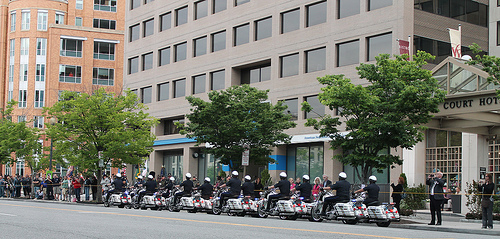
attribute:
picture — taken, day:
[35, 18, 485, 222]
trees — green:
[52, 94, 287, 177]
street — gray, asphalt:
[28, 203, 265, 238]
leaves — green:
[104, 109, 140, 141]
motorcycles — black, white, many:
[196, 192, 390, 220]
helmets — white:
[278, 170, 311, 178]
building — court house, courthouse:
[249, 10, 500, 174]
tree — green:
[342, 71, 432, 212]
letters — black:
[438, 97, 499, 111]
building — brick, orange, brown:
[14, 4, 119, 174]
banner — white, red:
[445, 25, 470, 66]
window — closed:
[207, 27, 229, 54]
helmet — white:
[361, 171, 378, 184]